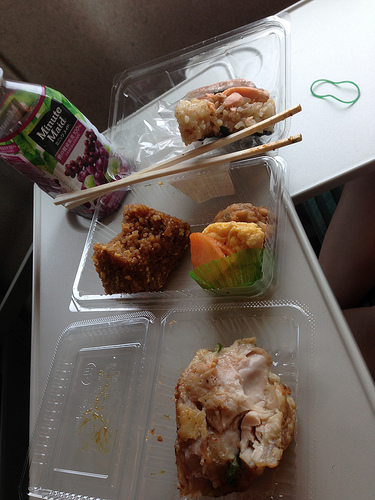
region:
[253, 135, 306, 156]
foot on the end of the chopsticks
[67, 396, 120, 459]
sauce on the plastic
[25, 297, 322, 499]
clear plastic container hanging open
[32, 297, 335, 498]
hunk of meat in a plastic container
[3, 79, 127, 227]
bottle of grape juice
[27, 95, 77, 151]
black and white minute maid logo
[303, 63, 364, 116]
green rubber band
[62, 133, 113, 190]
picture of grapes on the bottle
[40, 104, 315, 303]
two chopsticks laying on the box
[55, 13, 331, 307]
food in a plastic container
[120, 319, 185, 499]
plastic food container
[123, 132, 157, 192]
chopstick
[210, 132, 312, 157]
chopsticks sitting on the container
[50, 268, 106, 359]
containers are on a tray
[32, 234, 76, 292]
tray is white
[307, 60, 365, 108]
rubber band on the tray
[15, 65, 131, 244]
bottle of juice on the tray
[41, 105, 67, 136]
Minute Maid is written on the bottle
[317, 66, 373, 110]
rubber band is green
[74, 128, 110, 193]
picture of fruit on the bottle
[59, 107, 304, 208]
Pair of wooden chopsitcks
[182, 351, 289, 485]
Piece of half eaten meat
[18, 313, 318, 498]
A plastic package with a piece of meat inside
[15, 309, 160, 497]
The lid of a plastic container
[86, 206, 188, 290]
A type of dessert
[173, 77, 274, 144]
A piece of sushi containing rice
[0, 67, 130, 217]
A bottle of minute maid juice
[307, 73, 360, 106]
A green elastic band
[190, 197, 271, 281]
Food in a green cupcake wrapper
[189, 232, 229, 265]
Two pieces of orange food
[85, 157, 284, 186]
Chop sticks on the container.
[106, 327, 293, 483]
Meat in a plastic container.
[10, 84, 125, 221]
A juice bottle on the table.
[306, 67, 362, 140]
A rubber band on the table.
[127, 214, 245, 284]
Food in the plastic container.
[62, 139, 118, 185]
The juice bottle have grapes on it.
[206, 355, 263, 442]
A piece of chicken missing.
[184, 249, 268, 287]
The wrapper is gren.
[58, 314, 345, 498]
The container is open.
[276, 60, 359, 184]
The table is white.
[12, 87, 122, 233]
plastic bottle with grape juice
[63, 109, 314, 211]
light brown chopsticks are on container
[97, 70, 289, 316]
clear plastic container with biscuits inside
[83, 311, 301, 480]
clear container with meat sandwich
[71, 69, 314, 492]
two clear containers on white metal tray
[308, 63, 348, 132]
green rubber band is on white tray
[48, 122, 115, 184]
purple grapes are on plastic bottle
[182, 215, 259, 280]
orange muffin wrapped in green paper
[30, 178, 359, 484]
white tray is under food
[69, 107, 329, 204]
two chopsticks are used for eating